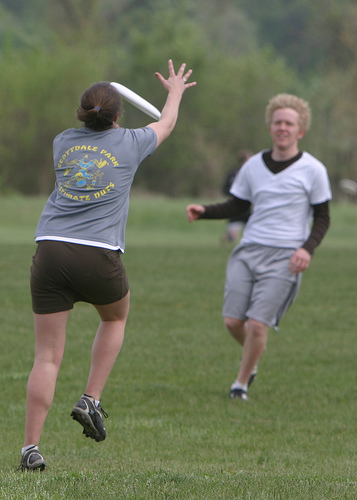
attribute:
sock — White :
[94, 400, 99, 406]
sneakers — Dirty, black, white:
[17, 399, 127, 470]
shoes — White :
[19, 393, 109, 470]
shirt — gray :
[44, 128, 139, 245]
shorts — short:
[22, 234, 134, 319]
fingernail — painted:
[153, 70, 159, 76]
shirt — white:
[229, 149, 332, 248]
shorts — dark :
[27, 236, 129, 317]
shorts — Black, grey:
[217, 237, 306, 328]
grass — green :
[6, 196, 355, 496]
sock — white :
[21, 444, 37, 457]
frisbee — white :
[108, 75, 163, 122]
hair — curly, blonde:
[265, 93, 312, 129]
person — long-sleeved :
[247, 86, 323, 171]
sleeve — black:
[301, 200, 328, 254]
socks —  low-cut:
[16, 441, 44, 457]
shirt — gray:
[25, 123, 154, 255]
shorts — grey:
[228, 246, 298, 330]